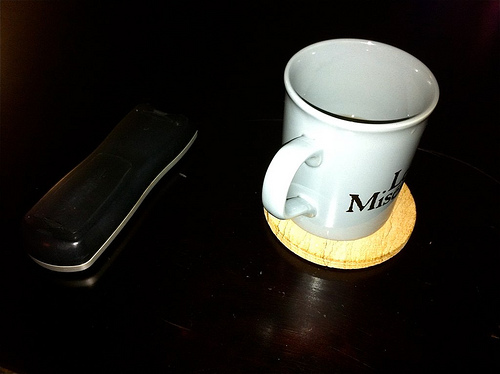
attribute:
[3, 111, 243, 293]
phone — silver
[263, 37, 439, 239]
glass — drinking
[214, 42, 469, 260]
coffee mug — white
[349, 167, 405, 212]
lettering — black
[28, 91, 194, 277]
remote — black and silver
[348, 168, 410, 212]
writing — black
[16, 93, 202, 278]
remote — black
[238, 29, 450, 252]
coffee mug — white and black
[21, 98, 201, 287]
phone bottom — black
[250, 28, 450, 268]
cup — white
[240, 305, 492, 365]
wood — Walnut colored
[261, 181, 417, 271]
coaster — brown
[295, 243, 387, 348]
coaster — brown